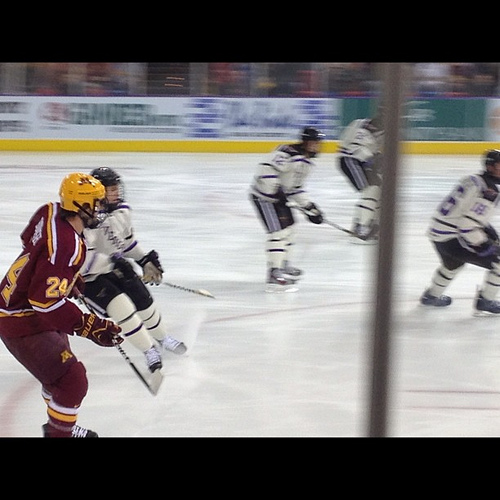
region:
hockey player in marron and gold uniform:
[0, 175, 130, 437]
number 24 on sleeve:
[44, 272, 70, 299]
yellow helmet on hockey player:
[55, 169, 105, 223]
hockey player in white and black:
[248, 122, 348, 293]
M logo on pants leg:
[58, 346, 73, 365]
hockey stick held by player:
[108, 340, 163, 397]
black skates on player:
[264, 262, 301, 299]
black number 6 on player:
[434, 183, 468, 216]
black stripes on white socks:
[117, 314, 156, 339]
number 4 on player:
[0, 256, 40, 305]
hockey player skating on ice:
[405, 249, 499, 337]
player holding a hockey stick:
[310, 205, 387, 248]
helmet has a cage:
[95, 175, 135, 203]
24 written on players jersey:
[45, 270, 71, 300]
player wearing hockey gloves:
[135, 247, 162, 284]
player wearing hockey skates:
[135, 330, 215, 381]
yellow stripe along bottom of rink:
[105, 140, 166, 147]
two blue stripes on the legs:
[116, 306, 146, 341]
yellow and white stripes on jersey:
[41, 201, 56, 236]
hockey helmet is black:
[305, 120, 320, 152]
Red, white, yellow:
[1, 174, 142, 446]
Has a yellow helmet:
[45, 163, 116, 237]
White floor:
[239, 316, 352, 423]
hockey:
[11, 100, 492, 438]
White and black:
[213, 111, 393, 322]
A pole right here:
[339, 71, 433, 439]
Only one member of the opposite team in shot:
[1, 147, 137, 453]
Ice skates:
[226, 235, 343, 309]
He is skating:
[58, 140, 195, 387]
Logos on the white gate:
[178, 89, 342, 150]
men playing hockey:
[3, 96, 496, 429]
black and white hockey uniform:
[244, 128, 336, 271]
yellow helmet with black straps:
[48, 168, 110, 231]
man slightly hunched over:
[233, 118, 382, 296]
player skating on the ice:
[412, 136, 499, 320]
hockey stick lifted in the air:
[310, 211, 387, 257]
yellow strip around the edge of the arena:
[3, 133, 499, 164]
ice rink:
[3, 147, 496, 448]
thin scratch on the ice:
[205, 286, 382, 340]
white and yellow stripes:
[66, 228, 89, 270]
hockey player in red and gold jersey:
[2, 173, 164, 436]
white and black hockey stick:
[111, 336, 164, 398]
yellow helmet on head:
[57, 170, 109, 232]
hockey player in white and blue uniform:
[248, 122, 378, 290]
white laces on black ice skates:
[69, 423, 98, 438]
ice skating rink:
[3, 148, 498, 433]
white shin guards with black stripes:
[104, 290, 167, 349]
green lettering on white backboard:
[39, 97, 186, 142]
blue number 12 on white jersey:
[269, 153, 287, 170]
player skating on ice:
[336, 103, 384, 241]